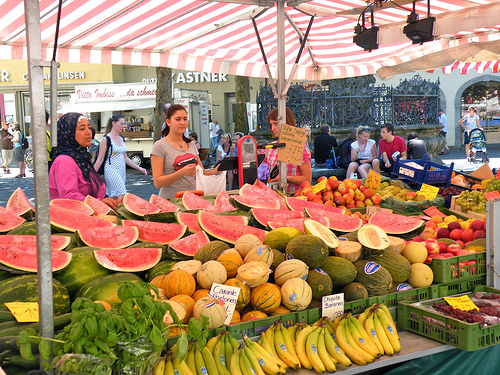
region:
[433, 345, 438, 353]
part of a table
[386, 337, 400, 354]
edge of a table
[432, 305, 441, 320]
part of a crate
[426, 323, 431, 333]
edge of a crate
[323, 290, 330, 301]
part of a mango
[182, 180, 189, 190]
part of a shirt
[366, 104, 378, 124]
part of a fence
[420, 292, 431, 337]
edge of a crate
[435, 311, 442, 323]
side of a crate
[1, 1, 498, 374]
marketplace loaded with a variety of fruits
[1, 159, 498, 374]
large assortment of fruits on display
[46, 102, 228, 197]
two women standing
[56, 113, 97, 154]
woman's head and neck covered with a wrap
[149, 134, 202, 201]
gray shirt on a young woman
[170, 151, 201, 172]
red lips graphic on a gray shirt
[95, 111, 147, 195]
woman wearing a white dress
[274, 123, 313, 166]
brown sale sign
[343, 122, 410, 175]
man and woman sitting down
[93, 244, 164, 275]
cut watermelon on display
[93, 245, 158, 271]
a sliced half of a pink and green watermelon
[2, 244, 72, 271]
a sliced half of a pink and green watermelon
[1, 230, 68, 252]
a sliced half of a pink and green watermelon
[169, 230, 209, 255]
a sliced half of a pink and green watermelon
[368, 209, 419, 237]
a sliced half of a pink and green watermelon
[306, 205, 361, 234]
a sliced half of a pink and green watermelon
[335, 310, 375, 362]
a bunch of yellow bananas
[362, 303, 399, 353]
a bunch of yellow bananas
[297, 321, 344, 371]
a bunch of yellow bananas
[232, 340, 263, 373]
a bunch of yellow bananas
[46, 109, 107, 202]
woman wearing a shawl on her head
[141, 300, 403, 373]
row of banana bunches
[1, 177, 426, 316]
watermelon quarters on a bed of whole watermelons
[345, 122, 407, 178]
man and woman sitting together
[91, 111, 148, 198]
woman walking with a backpack over her shoulder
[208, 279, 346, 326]
two signs indicating the types of fruit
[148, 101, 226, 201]
woman holding an open bag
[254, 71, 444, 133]
black wrought iron fencing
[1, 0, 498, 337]
canopy with supports covering fruit stall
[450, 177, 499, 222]
produce box containing grapes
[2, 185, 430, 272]
rows of water melon slices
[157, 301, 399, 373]
bunches of banaas in a row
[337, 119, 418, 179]
two people sitting on a bench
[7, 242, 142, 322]
three whole watermelons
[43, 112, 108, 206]
woman wearing pink shirt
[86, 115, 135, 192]
woman wearing white dress and carrying black backpack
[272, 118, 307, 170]
cardboard signs clipped to pole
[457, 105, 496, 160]
woman pushing a baby stroller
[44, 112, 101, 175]
head scarf of woman in pink shirt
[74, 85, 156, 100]
red lettering on white sign